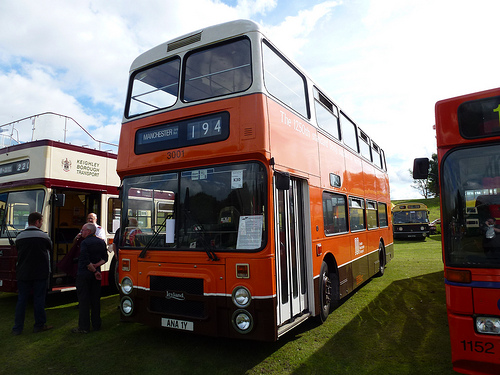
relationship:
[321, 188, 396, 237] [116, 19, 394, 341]
windows on bus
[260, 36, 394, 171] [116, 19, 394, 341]
windows on bus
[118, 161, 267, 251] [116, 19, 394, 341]
windshield on bus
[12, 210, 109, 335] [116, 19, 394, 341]
people standing next to bus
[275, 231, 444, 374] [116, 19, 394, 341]
grass next to bus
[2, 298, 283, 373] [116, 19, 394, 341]
grass in front of bus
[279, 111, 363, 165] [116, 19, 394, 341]
lettering on bus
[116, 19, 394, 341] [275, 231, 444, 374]
bus parked on grass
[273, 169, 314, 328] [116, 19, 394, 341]
door on bus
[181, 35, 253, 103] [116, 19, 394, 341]
window on bus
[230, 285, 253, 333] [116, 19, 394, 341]
headlights on bus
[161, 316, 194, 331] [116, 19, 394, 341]
license plate on bus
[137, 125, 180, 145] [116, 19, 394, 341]
sign on bus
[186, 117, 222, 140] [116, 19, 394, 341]
number on bus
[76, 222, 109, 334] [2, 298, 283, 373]
man standing on grass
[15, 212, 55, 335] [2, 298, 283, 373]
man standing in grass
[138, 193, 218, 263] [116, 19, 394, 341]
windshield wipers on bus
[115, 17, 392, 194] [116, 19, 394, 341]
top level on bus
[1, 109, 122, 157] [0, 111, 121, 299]
observation roof on bus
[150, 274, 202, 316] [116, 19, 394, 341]
grill on bus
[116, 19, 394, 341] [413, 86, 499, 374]
bus parked next to bus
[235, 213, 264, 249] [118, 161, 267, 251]
paper on windshield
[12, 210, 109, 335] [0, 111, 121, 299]
people standing next to bus